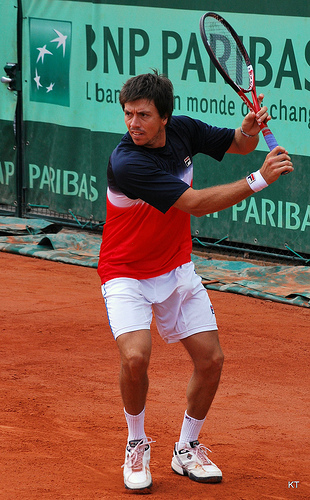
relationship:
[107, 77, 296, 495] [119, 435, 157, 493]
man wearing right foot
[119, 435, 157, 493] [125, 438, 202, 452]
right foot have black accents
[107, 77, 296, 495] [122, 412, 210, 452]
man wearing socks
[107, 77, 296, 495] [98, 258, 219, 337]
man wearing shorts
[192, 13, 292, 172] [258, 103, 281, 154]
racquet has handle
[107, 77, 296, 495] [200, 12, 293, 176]
man playing racquet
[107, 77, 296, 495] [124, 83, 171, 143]
man has face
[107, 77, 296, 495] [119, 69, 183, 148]
man has head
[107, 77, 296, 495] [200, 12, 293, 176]
man plays racquet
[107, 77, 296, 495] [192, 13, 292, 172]
man holding racket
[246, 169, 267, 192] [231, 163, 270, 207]
band on wrist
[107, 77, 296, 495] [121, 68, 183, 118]
man has hair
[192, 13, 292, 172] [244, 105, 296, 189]
racquet in hands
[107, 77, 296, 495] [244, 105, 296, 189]
man has hands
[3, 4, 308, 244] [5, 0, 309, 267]
sign on wall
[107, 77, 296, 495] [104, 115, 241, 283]
man wearing shirt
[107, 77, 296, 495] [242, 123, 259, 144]
man wears watch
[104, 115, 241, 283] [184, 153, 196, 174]
shirt has logo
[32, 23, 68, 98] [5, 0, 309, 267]
stars on wall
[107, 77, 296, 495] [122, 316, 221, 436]
man has legs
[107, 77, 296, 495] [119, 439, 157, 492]
man has right foot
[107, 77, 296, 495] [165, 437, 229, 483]
man has left foot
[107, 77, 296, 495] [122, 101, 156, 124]
man has eyes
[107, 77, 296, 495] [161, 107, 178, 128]
man has ear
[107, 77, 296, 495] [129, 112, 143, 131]
man has nose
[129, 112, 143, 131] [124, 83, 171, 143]
nose on face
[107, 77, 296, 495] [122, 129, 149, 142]
man has mouth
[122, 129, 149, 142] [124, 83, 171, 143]
mouth has face